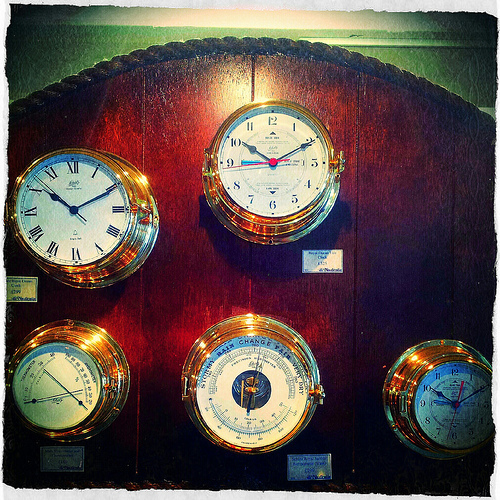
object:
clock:
[199, 99, 346, 247]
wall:
[12, 9, 494, 488]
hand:
[240, 139, 273, 164]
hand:
[275, 137, 317, 166]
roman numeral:
[67, 158, 80, 174]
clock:
[7, 144, 161, 289]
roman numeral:
[111, 204, 128, 214]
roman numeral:
[70, 246, 81, 261]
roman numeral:
[22, 206, 39, 217]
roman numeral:
[46, 239, 59, 255]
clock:
[381, 338, 491, 460]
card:
[299, 248, 345, 273]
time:
[240, 138, 316, 162]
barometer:
[179, 310, 325, 457]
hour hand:
[42, 188, 88, 221]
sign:
[8, 276, 41, 301]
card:
[286, 451, 333, 482]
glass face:
[217, 104, 333, 220]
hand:
[431, 387, 456, 408]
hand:
[459, 381, 492, 403]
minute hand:
[79, 183, 118, 208]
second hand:
[33, 173, 91, 228]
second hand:
[222, 157, 291, 171]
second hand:
[445, 379, 465, 437]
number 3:
[311, 160, 321, 170]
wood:
[8, 37, 496, 489]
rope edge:
[8, 33, 494, 133]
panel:
[6, 36, 493, 487]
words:
[310, 250, 335, 263]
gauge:
[14, 341, 104, 429]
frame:
[7, 318, 132, 443]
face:
[17, 154, 131, 266]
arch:
[62, 355, 96, 406]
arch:
[27, 356, 59, 407]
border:
[7, 274, 40, 305]